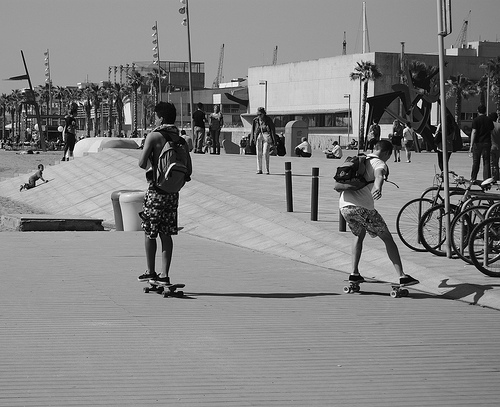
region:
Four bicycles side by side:
[393, 154, 498, 280]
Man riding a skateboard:
[126, 89, 205, 304]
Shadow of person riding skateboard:
[392, 249, 498, 309]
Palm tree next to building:
[346, 51, 380, 161]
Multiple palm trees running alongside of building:
[2, 68, 172, 145]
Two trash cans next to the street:
[94, 182, 149, 247]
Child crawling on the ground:
[15, 155, 67, 200]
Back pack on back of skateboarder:
[141, 128, 196, 192]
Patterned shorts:
[138, 186, 185, 239]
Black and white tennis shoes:
[136, 272, 177, 284]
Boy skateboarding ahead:
[119, 79, 214, 311]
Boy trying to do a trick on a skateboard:
[314, 118, 429, 338]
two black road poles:
[262, 140, 329, 225]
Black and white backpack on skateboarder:
[141, 114, 201, 206]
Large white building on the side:
[247, 52, 442, 161]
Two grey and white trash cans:
[104, 183, 165, 249]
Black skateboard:
[136, 264, 188, 311]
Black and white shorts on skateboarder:
[332, 193, 397, 245]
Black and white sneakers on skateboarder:
[343, 268, 423, 292]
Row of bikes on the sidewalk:
[397, 176, 499, 259]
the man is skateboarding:
[131, 88, 211, 303]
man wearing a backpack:
[143, 126, 191, 202]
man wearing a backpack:
[324, 130, 398, 206]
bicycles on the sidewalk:
[386, 156, 498, 277]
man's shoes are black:
[127, 264, 182, 291]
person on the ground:
[17, 155, 61, 212]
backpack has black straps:
[147, 121, 192, 155]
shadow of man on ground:
[175, 269, 340, 304]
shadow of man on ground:
[388, 276, 498, 318]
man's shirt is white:
[332, 141, 392, 212]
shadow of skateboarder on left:
[180, 276, 341, 306]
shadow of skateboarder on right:
[358, 270, 498, 305]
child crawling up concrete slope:
[15, 158, 57, 194]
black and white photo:
[2, 1, 498, 405]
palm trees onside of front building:
[351, 53, 498, 159]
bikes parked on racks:
[391, 165, 499, 280]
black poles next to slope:
[281, 155, 354, 230]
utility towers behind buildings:
[206, 8, 498, 81]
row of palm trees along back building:
[2, 70, 160, 152]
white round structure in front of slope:
[108, 183, 151, 230]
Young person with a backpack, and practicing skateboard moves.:
[330, 138, 414, 299]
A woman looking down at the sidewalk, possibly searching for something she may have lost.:
[250, 104, 277, 175]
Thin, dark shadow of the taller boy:
[185, 288, 342, 299]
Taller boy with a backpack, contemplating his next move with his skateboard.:
[135, 96, 195, 298]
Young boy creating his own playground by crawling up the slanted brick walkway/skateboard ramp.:
[18, 161, 50, 191]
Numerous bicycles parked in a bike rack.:
[395, 169, 497, 276]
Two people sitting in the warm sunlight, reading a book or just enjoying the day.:
[293, 135, 343, 157]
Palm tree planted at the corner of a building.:
[349, 59, 380, 155]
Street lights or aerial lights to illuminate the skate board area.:
[147, 22, 165, 102]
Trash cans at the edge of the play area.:
[108, 187, 148, 230]